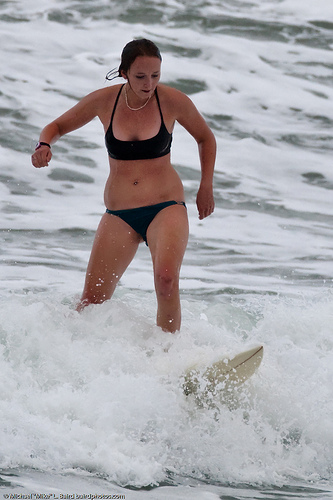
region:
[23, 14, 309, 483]
woman on surfboard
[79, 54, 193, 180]
woman wearing black top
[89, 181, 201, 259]
woman wearing black bottom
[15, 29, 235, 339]
woman wearing bikini with string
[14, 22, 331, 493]
woman riding surfboard on wave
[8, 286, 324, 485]
surfboard is white with line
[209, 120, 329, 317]
white foam on water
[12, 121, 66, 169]
woman wearing black watch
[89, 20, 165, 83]
woman has black hair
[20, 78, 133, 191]
right arm is extended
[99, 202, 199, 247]
black bathing suit bottoms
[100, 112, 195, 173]
black bathing suit tops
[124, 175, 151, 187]
belly button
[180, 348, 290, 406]
tip of white surfboard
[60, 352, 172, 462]
waves crashing together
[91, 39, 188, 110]
woman with hair tied back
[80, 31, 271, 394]
woman surfing on a surf board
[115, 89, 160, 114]
white necklace on neck and chest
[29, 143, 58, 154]
black watch on wrist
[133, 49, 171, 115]
woman with eyes closed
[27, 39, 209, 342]
woman surfing on white board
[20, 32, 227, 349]
woman wearing black bikini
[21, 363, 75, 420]
white and green ocean waves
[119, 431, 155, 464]
white and green ocean waves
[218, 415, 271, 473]
white and green ocean waves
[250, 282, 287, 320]
white and green ocean waves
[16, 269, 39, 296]
white and green ocean waves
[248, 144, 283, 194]
white and green ocean waves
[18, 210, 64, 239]
white and green ocean waves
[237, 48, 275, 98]
white and green ocean waves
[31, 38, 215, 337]
a lady wearing a swim suit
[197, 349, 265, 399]
the tip of the surf board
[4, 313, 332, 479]
waves in the water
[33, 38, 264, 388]
a woman on a surf board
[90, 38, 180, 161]
a woman wearing a necklace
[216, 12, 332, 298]
water in the background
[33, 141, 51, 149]
a watch on the womans hand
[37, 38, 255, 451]
a lady standing in water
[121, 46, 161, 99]
the face of the woman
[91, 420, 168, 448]
water droplets from the splash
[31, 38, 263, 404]
the woman surfing in the water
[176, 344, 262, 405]
the tip of the surfboard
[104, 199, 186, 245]
the bottom bikini on the woman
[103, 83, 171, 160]
the top bikini on the woman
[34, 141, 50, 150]
the watch on the woman's wrist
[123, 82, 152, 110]
the necklace on the woman's neck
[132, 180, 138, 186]
the woman's belly button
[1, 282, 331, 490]
the water splashing around the woman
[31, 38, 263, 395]
the woman surfing in the ocean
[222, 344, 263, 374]
the line on the back of the surfboard